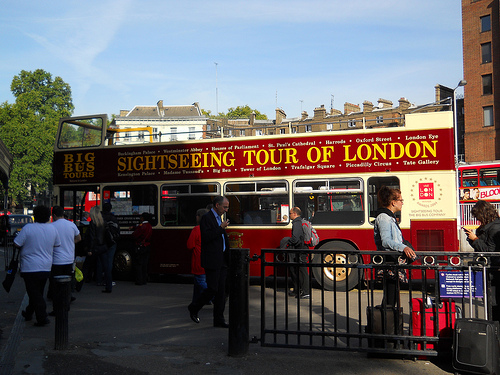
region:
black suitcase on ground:
[451, 314, 498, 372]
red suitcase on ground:
[404, 298, 456, 352]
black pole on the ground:
[226, 246, 252, 362]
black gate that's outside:
[262, 246, 456, 355]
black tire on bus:
[310, 241, 359, 293]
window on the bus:
[299, 179, 363, 227]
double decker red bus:
[57, 115, 459, 287]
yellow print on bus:
[60, 153, 102, 178]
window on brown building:
[479, 41, 491, 69]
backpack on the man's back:
[303, 219, 319, 245]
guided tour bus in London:
[26, 98, 470, 291]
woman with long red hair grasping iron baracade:
[366, 178, 429, 364]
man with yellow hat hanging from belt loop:
[46, 194, 91, 312]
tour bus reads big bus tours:
[48, 146, 110, 190]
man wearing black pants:
[278, 200, 323, 307]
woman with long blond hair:
[71, 199, 137, 296]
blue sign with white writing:
[408, 265, 498, 308]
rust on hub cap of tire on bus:
[318, 245, 352, 282]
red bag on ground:
[404, 286, 471, 361]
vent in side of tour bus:
[413, 225, 451, 277]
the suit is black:
[193, 218, 239, 318]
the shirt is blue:
[214, 212, 238, 252]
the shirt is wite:
[15, 224, 57, 279]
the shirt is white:
[52, 217, 80, 262]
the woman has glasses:
[357, 188, 427, 275]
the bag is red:
[408, 294, 462, 351]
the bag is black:
[448, 317, 498, 367]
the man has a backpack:
[281, 209, 329, 298]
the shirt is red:
[186, 229, 209, 279]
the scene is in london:
[8, 4, 498, 372]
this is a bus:
[91, 125, 377, 191]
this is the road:
[118, 291, 178, 368]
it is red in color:
[340, 130, 370, 171]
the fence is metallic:
[366, 253, 416, 346]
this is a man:
[203, 197, 238, 247]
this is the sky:
[259, 8, 366, 66]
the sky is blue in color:
[276, 5, 339, 72]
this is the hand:
[370, 235, 402, 254]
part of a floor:
[146, 338, 163, 360]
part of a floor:
[161, 346, 181, 371]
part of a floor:
[151, 312, 173, 339]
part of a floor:
[168, 334, 190, 355]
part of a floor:
[176, 328, 192, 343]